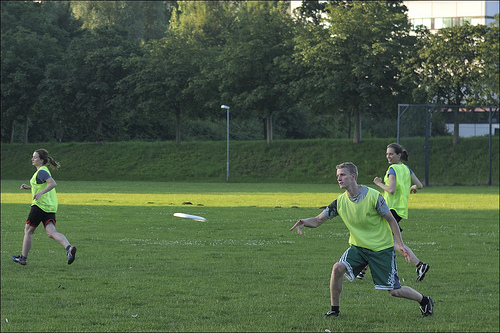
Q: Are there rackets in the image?
A: No, there are no rackets.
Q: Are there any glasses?
A: No, there are no glasses.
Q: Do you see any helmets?
A: No, there are no helmets.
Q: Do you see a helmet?
A: No, there are no helmets.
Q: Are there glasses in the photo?
A: No, there are no glasses.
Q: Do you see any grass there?
A: Yes, there is grass.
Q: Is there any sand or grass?
A: Yes, there is grass.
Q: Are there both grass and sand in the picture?
A: No, there is grass but no sand.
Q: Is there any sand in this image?
A: No, there is no sand.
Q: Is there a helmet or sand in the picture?
A: No, there are no sand or helmets.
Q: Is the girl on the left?
A: Yes, the girl is on the left of the image.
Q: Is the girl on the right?
A: No, the girl is on the left of the image.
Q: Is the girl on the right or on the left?
A: The girl is on the left of the image.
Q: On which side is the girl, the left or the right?
A: The girl is on the left of the image.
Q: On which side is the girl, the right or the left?
A: The girl is on the left of the image.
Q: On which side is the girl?
A: The girl is on the left of the image.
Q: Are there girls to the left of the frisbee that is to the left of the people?
A: Yes, there is a girl to the left of the frisbee.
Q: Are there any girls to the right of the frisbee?
A: No, the girl is to the left of the frisbee.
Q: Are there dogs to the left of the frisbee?
A: No, there is a girl to the left of the frisbee.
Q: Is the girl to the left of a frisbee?
A: Yes, the girl is to the left of a frisbee.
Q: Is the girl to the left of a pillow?
A: No, the girl is to the left of a frisbee.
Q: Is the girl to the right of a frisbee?
A: No, the girl is to the left of a frisbee.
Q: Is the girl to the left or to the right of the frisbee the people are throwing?
A: The girl is to the left of the frisbee.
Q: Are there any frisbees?
A: Yes, there is a frisbee.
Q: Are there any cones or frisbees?
A: Yes, there is a frisbee.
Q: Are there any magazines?
A: No, there are no magazines.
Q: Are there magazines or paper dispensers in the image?
A: No, there are no magazines or paper dispensers.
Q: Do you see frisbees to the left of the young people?
A: Yes, there is a frisbee to the left of the people.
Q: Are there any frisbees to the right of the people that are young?
A: No, the frisbee is to the left of the people.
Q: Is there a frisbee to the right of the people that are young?
A: No, the frisbee is to the left of the people.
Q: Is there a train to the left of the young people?
A: No, there is a frisbee to the left of the people.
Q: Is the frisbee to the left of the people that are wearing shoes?
A: Yes, the frisbee is to the left of the people.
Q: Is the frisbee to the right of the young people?
A: No, the frisbee is to the left of the people.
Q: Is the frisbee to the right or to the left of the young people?
A: The frisbee is to the left of the people.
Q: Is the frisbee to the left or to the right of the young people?
A: The frisbee is to the left of the people.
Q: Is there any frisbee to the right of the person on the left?
A: Yes, there is a frisbee to the right of the girl.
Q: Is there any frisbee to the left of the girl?
A: No, the frisbee is to the right of the girl.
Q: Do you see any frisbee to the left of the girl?
A: No, the frisbee is to the right of the girl.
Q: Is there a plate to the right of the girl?
A: No, there is a frisbee to the right of the girl.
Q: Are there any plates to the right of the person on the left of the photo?
A: No, there is a frisbee to the right of the girl.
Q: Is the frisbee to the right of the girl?
A: Yes, the frisbee is to the right of the girl.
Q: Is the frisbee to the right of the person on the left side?
A: Yes, the frisbee is to the right of the girl.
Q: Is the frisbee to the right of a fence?
A: No, the frisbee is to the right of the girl.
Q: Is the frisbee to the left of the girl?
A: No, the frisbee is to the right of the girl.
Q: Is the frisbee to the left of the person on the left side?
A: No, the frisbee is to the right of the girl.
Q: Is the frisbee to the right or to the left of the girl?
A: The frisbee is to the right of the girl.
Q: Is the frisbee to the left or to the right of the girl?
A: The frisbee is to the right of the girl.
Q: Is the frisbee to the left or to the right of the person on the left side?
A: The frisbee is to the right of the girl.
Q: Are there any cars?
A: No, there are no cars.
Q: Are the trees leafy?
A: Yes, the trees are leafy.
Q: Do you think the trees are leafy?
A: Yes, the trees are leafy.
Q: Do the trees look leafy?
A: Yes, the trees are leafy.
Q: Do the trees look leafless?
A: No, the trees are leafy.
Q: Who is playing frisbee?
A: The people are playing frisbee.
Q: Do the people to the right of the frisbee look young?
A: Yes, the people are young.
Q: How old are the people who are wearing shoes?
A: The people are young.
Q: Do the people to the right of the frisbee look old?
A: No, the people are young.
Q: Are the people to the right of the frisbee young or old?
A: The people are young.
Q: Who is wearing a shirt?
A: The people are wearing a shirt.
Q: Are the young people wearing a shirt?
A: Yes, the people are wearing a shirt.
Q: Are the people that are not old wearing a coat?
A: No, the people are wearing a shirt.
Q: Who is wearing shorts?
A: The people are wearing shorts.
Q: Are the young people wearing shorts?
A: Yes, the people are wearing shorts.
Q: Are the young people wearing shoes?
A: Yes, the people are wearing shoes.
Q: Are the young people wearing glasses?
A: No, the people are wearing shoes.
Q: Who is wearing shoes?
A: The people are wearing shoes.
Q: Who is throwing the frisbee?
A: The people are throwing the frisbee.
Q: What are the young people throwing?
A: The people are throwing the frisbee.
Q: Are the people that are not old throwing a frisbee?
A: Yes, the people are throwing a frisbee.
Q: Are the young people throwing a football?
A: No, the people are throwing a frisbee.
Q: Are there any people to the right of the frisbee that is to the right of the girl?
A: Yes, there are people to the right of the frisbee.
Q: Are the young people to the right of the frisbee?
A: Yes, the people are to the right of the frisbee.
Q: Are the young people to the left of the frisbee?
A: No, the people are to the right of the frisbee.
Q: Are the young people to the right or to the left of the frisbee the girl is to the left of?
A: The people are to the right of the frisbee.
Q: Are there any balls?
A: No, there are no balls.